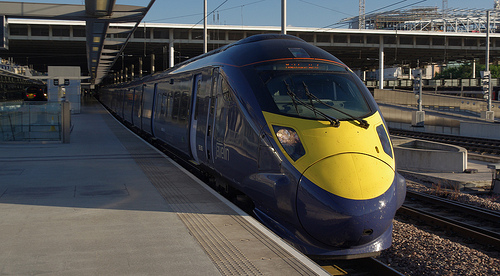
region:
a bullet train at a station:
[133, 45, 428, 251]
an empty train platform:
[7, 140, 273, 275]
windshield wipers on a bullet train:
[295, 77, 370, 134]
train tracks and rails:
[418, 194, 492, 250]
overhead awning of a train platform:
[75, 0, 129, 96]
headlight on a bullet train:
[272, 122, 307, 163]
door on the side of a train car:
[184, 73, 208, 160]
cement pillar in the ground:
[400, 132, 477, 185]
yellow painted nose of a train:
[315, 135, 369, 185]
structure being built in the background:
[367, 9, 488, 84]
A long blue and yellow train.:
[96, 30, 407, 260]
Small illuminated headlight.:
[276, 128, 293, 142]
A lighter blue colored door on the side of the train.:
[188, 71, 201, 167]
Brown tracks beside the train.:
[403, 190, 498, 246]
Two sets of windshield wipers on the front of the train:
[281, 78, 370, 128]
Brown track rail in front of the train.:
[369, 255, 401, 274]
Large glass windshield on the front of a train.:
[241, 56, 374, 125]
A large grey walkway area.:
[0, 98, 316, 274]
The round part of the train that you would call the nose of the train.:
[294, 147, 399, 249]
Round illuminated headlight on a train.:
[276, 126, 293, 143]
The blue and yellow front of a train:
[210, 28, 430, 271]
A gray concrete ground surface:
[34, 162, 181, 274]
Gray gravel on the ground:
[416, 238, 471, 273]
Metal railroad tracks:
[409, 186, 499, 256]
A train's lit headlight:
[265, 118, 315, 167]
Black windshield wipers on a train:
[282, 74, 368, 139]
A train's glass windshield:
[250, 63, 380, 128]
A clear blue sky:
[294, 3, 328, 27]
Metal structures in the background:
[361, 7, 496, 33]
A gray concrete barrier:
[400, 132, 474, 181]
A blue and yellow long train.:
[95, 31, 409, 258]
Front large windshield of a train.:
[249, 64, 372, 124]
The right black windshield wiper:
[303, 81, 369, 128]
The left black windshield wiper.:
[279, 79, 340, 127]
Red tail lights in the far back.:
[25, 91, 37, 96]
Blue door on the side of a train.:
[188, 70, 203, 164]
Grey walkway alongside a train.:
[6, 94, 318, 274]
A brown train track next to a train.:
[398, 187, 498, 248]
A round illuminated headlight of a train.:
[276, 129, 295, 146]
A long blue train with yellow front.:
[95, 30, 406, 260]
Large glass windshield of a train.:
[241, 60, 371, 120]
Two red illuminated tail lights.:
[25, 90, 36, 97]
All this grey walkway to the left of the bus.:
[3, 95, 325, 275]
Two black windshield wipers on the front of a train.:
[283, 78, 369, 129]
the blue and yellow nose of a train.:
[295, 151, 400, 248]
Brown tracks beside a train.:
[399, 186, 498, 243]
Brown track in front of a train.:
[367, 256, 401, 274]